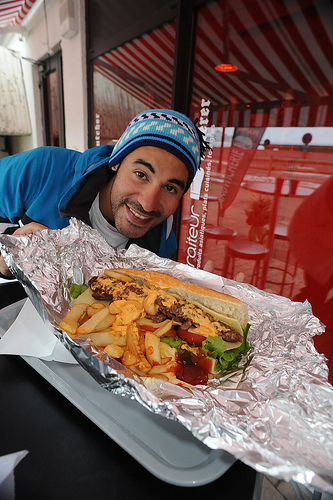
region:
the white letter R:
[184, 199, 206, 217]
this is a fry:
[139, 324, 167, 369]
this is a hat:
[95, 91, 217, 218]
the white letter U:
[187, 211, 204, 230]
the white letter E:
[185, 221, 204, 237]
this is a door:
[94, 251, 265, 341]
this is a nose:
[136, 178, 165, 214]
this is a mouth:
[119, 200, 157, 229]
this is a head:
[92, 101, 207, 242]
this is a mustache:
[126, 192, 165, 221]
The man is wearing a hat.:
[110, 101, 201, 241]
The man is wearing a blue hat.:
[107, 110, 211, 245]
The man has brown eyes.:
[132, 154, 185, 196]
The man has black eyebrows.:
[130, 156, 189, 203]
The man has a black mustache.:
[122, 194, 166, 229]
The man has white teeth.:
[124, 202, 156, 228]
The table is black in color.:
[40, 449, 99, 498]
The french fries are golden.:
[62, 304, 129, 354]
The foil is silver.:
[234, 401, 313, 442]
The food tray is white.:
[138, 432, 190, 463]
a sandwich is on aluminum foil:
[10, 217, 324, 456]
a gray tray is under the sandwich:
[1, 274, 253, 488]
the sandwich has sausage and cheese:
[87, 264, 245, 348]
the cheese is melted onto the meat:
[87, 272, 230, 350]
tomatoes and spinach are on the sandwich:
[142, 312, 249, 371]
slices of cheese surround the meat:
[77, 288, 249, 351]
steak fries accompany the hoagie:
[59, 295, 177, 382]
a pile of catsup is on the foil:
[166, 352, 223, 393]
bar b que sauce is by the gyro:
[172, 352, 214, 389]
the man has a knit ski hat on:
[107, 105, 208, 177]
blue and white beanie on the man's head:
[108, 109, 208, 179]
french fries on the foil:
[62, 301, 178, 378]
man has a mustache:
[126, 199, 163, 219]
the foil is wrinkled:
[6, 221, 332, 492]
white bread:
[113, 267, 247, 329]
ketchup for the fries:
[174, 351, 208, 385]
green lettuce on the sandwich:
[166, 334, 250, 364]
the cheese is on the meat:
[97, 277, 224, 344]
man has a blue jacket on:
[5, 145, 187, 254]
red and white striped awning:
[0, 0, 34, 25]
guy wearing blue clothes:
[1, 103, 206, 277]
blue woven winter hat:
[101, 104, 212, 198]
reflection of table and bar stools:
[192, 163, 329, 303]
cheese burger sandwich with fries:
[53, 257, 257, 401]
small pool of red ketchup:
[171, 343, 215, 388]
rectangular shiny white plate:
[1, 294, 243, 492]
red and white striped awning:
[0, 0, 41, 34]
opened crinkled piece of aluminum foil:
[3, 215, 329, 484]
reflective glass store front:
[77, 2, 331, 300]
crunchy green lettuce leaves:
[201, 329, 252, 372]